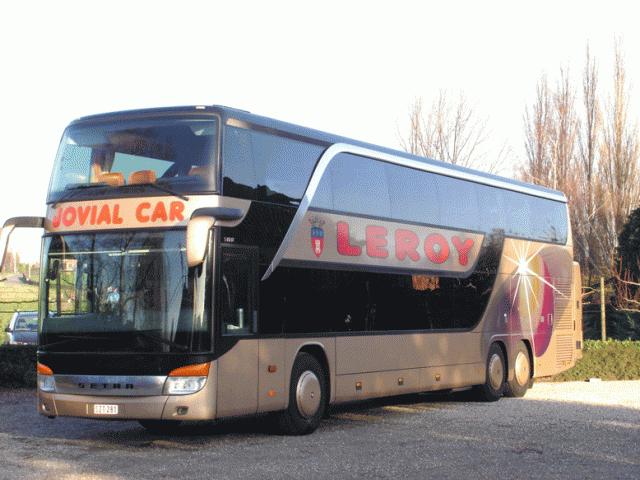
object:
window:
[223, 125, 258, 201]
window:
[253, 126, 335, 210]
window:
[266, 132, 334, 210]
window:
[331, 151, 391, 218]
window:
[385, 162, 441, 226]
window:
[434, 173, 481, 231]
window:
[476, 183, 508, 235]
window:
[505, 190, 534, 239]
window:
[259, 263, 320, 334]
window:
[37, 226, 212, 352]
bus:
[0, 105, 584, 436]